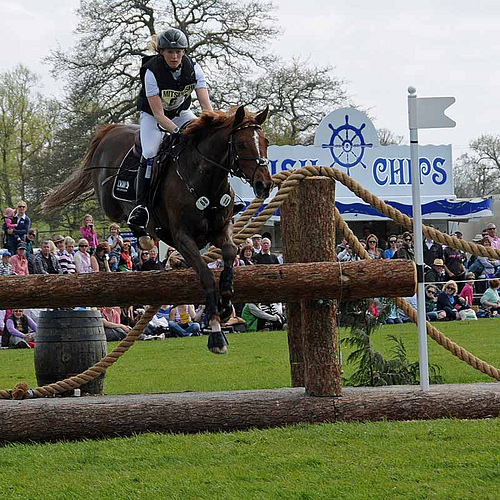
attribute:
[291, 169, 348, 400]
pole — wood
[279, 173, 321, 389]
pole — wood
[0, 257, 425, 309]
pole — wood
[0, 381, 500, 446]
pole — wood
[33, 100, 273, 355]
horse — brown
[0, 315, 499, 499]
grass — green, neat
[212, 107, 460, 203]
sign — white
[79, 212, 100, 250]
person — crowd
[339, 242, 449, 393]
bush — green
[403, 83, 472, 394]
pole — white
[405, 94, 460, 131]
flag — white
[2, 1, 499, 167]
clouds — white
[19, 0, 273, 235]
tree — bare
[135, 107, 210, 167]
pants — white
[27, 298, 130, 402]
barrel — wood, brown, wooden